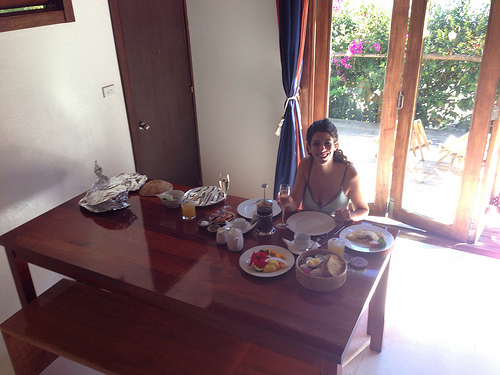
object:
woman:
[277, 119, 370, 222]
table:
[0, 175, 401, 375]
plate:
[286, 210, 335, 235]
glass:
[276, 184, 291, 229]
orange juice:
[182, 203, 196, 217]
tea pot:
[227, 227, 244, 252]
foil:
[78, 160, 148, 213]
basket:
[294, 249, 347, 292]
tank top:
[301, 160, 352, 216]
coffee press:
[255, 184, 276, 235]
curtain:
[272, 1, 307, 206]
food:
[249, 247, 289, 272]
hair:
[305, 118, 353, 165]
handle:
[138, 121, 151, 131]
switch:
[102, 84, 115, 98]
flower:
[349, 41, 363, 54]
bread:
[321, 255, 344, 277]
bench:
[0, 277, 331, 374]